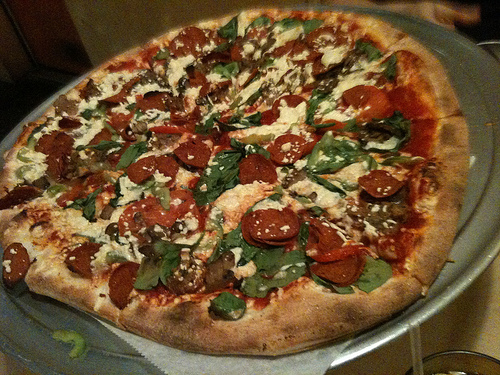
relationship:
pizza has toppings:
[184, 44, 238, 76] [315, 175, 369, 221]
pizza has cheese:
[184, 44, 238, 76] [258, 89, 309, 122]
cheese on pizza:
[258, 89, 309, 122] [184, 44, 238, 76]